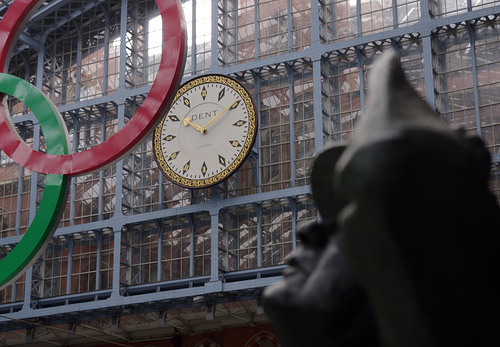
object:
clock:
[148, 70, 263, 192]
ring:
[0, 69, 78, 296]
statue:
[254, 39, 499, 293]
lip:
[275, 248, 315, 284]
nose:
[292, 213, 334, 253]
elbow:
[326, 48, 500, 206]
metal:
[304, 34, 345, 114]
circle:
[0, 4, 191, 182]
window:
[217, 1, 315, 68]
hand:
[181, 115, 208, 135]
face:
[255, 189, 380, 341]